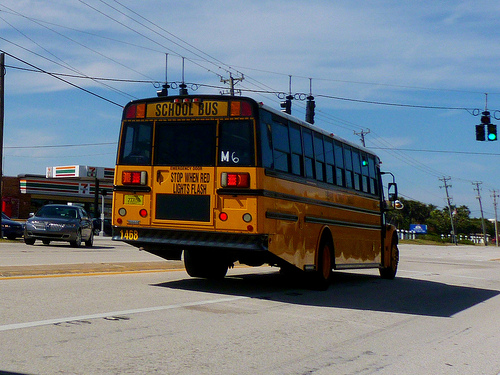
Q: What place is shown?
A: It is a street.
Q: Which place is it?
A: It is a street.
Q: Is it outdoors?
A: Yes, it is outdoors.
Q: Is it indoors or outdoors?
A: It is outdoors.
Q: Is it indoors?
A: No, it is outdoors.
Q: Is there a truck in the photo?
A: No, there are no trucks.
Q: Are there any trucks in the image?
A: No, there are no trucks.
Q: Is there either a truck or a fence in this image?
A: No, there are no trucks or fences.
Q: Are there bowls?
A: No, there are no bowls.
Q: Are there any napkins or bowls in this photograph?
A: No, there are no bowls or napkins.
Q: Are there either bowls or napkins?
A: No, there are no bowls or napkins.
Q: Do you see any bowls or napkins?
A: No, there are no bowls or napkins.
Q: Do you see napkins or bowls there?
A: No, there are no bowls or napkins.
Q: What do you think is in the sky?
A: The clouds are in the sky.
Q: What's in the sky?
A: The clouds are in the sky.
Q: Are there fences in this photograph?
A: No, there are no fences.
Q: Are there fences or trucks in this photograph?
A: No, there are no fences or trucks.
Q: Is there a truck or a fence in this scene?
A: No, there are no fences or trucks.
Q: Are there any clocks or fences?
A: No, there are no fences or clocks.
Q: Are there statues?
A: No, there are no statues.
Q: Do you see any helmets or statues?
A: No, there are no statues or helmets.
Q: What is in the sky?
A: The clouds are in the sky.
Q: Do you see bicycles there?
A: No, there are no bicycles.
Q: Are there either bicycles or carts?
A: No, there are no bicycles or carts.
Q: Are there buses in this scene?
A: Yes, there is a bus.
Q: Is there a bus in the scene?
A: Yes, there is a bus.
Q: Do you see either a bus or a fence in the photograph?
A: Yes, there is a bus.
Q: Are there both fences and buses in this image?
A: No, there is a bus but no fences.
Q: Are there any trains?
A: No, there are no trains.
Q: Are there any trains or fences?
A: No, there are no trains or fences.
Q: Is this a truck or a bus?
A: This is a bus.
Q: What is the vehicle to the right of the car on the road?
A: The vehicle is a bus.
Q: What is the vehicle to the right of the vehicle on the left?
A: The vehicle is a bus.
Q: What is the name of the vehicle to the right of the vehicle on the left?
A: The vehicle is a bus.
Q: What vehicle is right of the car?
A: The vehicle is a bus.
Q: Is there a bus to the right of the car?
A: Yes, there is a bus to the right of the car.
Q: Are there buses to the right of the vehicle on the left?
A: Yes, there is a bus to the right of the car.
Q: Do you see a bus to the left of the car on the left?
A: No, the bus is to the right of the car.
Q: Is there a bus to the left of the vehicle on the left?
A: No, the bus is to the right of the car.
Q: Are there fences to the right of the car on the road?
A: No, there is a bus to the right of the car.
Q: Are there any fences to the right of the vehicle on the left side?
A: No, there is a bus to the right of the car.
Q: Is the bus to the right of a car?
A: Yes, the bus is to the right of a car.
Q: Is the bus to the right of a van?
A: No, the bus is to the right of a car.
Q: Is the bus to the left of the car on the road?
A: No, the bus is to the right of the car.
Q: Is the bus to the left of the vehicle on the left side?
A: No, the bus is to the right of the car.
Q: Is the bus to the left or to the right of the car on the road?
A: The bus is to the right of the car.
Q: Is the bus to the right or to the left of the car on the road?
A: The bus is to the right of the car.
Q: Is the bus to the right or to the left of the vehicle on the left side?
A: The bus is to the right of the car.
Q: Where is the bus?
A: The bus is on the road.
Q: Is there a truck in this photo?
A: No, there are no trucks.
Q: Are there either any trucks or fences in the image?
A: No, there are no trucks or fences.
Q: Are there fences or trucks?
A: No, there are no trucks or fences.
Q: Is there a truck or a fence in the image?
A: No, there are no trucks or fences.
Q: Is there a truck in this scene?
A: No, there are no trucks.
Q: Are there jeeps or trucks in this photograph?
A: No, there are no trucks or jeeps.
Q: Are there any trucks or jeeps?
A: No, there are no trucks or jeeps.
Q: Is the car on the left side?
A: Yes, the car is on the left of the image.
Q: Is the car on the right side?
A: No, the car is on the left of the image.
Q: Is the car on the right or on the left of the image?
A: The car is on the left of the image.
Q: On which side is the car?
A: The car is on the left of the image.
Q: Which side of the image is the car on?
A: The car is on the left of the image.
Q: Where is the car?
A: The car is on the road.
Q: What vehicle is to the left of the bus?
A: The vehicle is a car.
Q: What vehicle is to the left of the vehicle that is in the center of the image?
A: The vehicle is a car.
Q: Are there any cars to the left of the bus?
A: Yes, there is a car to the left of the bus.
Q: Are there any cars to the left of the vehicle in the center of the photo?
A: Yes, there is a car to the left of the bus.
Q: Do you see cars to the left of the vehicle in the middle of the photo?
A: Yes, there is a car to the left of the bus.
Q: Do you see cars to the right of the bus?
A: No, the car is to the left of the bus.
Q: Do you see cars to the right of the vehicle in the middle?
A: No, the car is to the left of the bus.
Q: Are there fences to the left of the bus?
A: No, there is a car to the left of the bus.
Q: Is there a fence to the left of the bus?
A: No, there is a car to the left of the bus.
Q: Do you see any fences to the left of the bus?
A: No, there is a car to the left of the bus.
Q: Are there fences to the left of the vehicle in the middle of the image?
A: No, there is a car to the left of the bus.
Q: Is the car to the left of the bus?
A: Yes, the car is to the left of the bus.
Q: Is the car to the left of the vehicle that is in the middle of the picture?
A: Yes, the car is to the left of the bus.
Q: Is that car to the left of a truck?
A: No, the car is to the left of the bus.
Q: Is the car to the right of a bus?
A: No, the car is to the left of a bus.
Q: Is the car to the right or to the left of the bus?
A: The car is to the left of the bus.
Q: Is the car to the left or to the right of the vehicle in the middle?
A: The car is to the left of the bus.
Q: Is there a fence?
A: No, there are no fences.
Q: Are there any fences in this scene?
A: No, there are no fences.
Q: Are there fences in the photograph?
A: No, there are no fences.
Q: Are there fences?
A: No, there are no fences.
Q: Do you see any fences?
A: No, there are no fences.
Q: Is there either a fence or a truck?
A: No, there are no fences or trucks.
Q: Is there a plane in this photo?
A: No, there are no airplanes.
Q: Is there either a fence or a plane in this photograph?
A: No, there are no airplanes or fences.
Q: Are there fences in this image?
A: No, there are no fences.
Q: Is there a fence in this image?
A: No, there are no fences.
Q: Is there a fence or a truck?
A: No, there are no fences or trucks.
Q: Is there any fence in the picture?
A: No, there are no fences.